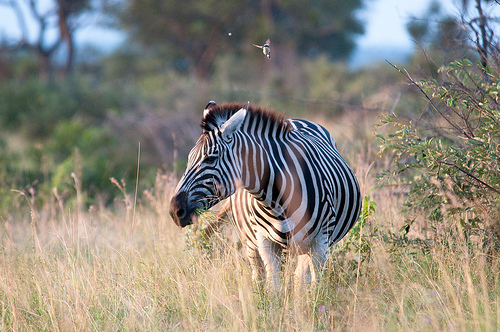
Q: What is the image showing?
A: It is showing a field.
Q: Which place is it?
A: It is a field.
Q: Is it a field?
A: Yes, it is a field.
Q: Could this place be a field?
A: Yes, it is a field.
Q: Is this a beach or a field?
A: It is a field.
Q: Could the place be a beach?
A: No, it is a field.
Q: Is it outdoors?
A: Yes, it is outdoors.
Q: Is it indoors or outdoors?
A: It is outdoors.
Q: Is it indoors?
A: No, it is outdoors.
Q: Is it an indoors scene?
A: No, it is outdoors.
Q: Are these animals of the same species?
A: No, they are birds and zebras.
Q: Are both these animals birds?
A: No, they are birds and zebras.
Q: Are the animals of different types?
A: Yes, they are birds and zebras.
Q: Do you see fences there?
A: No, there are no fences.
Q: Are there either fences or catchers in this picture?
A: No, there are no fences or catchers.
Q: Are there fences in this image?
A: No, there are no fences.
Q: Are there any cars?
A: No, there are no cars.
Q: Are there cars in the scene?
A: No, there are no cars.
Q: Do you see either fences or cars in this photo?
A: No, there are no cars or fences.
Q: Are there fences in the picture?
A: No, there are no fences.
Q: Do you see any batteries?
A: No, there are no batteries.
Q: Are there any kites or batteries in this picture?
A: No, there are no batteries or kites.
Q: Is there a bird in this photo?
A: Yes, there is a bird.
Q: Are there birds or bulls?
A: Yes, there is a bird.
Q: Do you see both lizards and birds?
A: No, there is a bird but no lizards.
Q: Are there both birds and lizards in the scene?
A: No, there is a bird but no lizards.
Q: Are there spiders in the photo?
A: No, there are no spiders.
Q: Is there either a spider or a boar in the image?
A: No, there are no spiders or boars.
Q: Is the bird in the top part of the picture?
A: Yes, the bird is in the top of the image.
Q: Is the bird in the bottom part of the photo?
A: No, the bird is in the top of the image.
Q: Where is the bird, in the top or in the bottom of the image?
A: The bird is in the top of the image.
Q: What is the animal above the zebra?
A: The animal is a bird.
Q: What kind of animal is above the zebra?
A: The animal is a bird.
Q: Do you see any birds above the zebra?
A: Yes, there is a bird above the zebra.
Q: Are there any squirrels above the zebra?
A: No, there is a bird above the zebra.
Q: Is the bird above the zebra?
A: Yes, the bird is above the zebra.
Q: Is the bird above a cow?
A: No, the bird is above the zebra.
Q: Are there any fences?
A: No, there are no fences.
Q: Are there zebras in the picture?
A: Yes, there is a zebra.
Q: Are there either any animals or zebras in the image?
A: Yes, there is a zebra.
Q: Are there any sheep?
A: No, there are no sheep.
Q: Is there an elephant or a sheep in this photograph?
A: No, there are no sheep or elephants.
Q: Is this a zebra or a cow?
A: This is a zebra.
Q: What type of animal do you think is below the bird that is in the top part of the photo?
A: The animal is a zebra.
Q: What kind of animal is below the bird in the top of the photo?
A: The animal is a zebra.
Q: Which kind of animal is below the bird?
A: The animal is a zebra.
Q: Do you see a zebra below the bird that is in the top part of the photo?
A: Yes, there is a zebra below the bird.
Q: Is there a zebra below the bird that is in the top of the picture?
A: Yes, there is a zebra below the bird.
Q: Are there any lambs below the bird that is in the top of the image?
A: No, there is a zebra below the bird.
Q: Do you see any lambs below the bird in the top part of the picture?
A: No, there is a zebra below the bird.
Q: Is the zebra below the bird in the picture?
A: Yes, the zebra is below the bird.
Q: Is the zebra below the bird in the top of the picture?
A: Yes, the zebra is below the bird.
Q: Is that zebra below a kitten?
A: No, the zebra is below the bird.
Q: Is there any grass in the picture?
A: Yes, there is grass.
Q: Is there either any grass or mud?
A: Yes, there is grass.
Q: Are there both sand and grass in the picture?
A: No, there is grass but no sand.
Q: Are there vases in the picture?
A: No, there are no vases.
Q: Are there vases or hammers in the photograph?
A: No, there are no vases or hammers.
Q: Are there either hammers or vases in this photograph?
A: No, there are no vases or hammers.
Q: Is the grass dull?
A: Yes, the grass is dull.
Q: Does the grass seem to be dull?
A: Yes, the grass is dull.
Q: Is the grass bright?
A: No, the grass is dull.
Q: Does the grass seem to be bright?
A: No, the grass is dull.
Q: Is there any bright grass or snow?
A: No, there is grass but it is dull.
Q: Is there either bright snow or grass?
A: No, there is grass but it is dull.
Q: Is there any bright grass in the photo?
A: No, there is grass but it is dull.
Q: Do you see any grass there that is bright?
A: No, there is grass but it is dull.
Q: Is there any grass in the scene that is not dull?
A: No, there is grass but it is dull.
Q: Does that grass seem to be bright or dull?
A: The grass is dull.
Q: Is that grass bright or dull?
A: The grass is dull.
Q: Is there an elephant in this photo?
A: No, there are no elephants.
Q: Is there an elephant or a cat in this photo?
A: No, there are no elephants or cats.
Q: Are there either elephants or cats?
A: No, there are no elephants or cats.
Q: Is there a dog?
A: No, there are no dogs.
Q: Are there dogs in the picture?
A: No, there are no dogs.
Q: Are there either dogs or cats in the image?
A: No, there are no dogs or cats.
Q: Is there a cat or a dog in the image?
A: No, there are no dogs or cats.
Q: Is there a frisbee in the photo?
A: No, there are no frisbees.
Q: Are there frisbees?
A: No, there are no frisbees.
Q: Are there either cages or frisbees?
A: No, there are no frisbees or cages.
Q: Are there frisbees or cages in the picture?
A: No, there are no frisbees or cages.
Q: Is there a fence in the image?
A: No, there are no fences.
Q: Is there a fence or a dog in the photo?
A: No, there are no fences or dogs.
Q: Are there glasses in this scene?
A: No, there are no glasses.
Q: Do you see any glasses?
A: No, there are no glasses.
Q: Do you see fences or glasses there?
A: No, there are no glasses or fences.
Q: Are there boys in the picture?
A: No, there are no boys.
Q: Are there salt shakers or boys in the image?
A: No, there are no boys or salt shakers.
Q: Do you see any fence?
A: No, there are no fences.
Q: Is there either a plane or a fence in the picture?
A: No, there are no fences or airplanes.